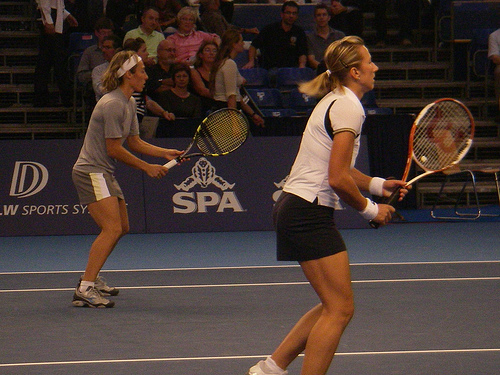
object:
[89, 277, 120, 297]
tennis shoes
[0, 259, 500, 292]
lines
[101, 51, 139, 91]
hair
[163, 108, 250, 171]
racket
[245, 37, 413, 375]
woman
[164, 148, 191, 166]
hand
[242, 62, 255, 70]
hand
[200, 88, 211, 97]
hand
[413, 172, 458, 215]
ground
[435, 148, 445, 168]
ground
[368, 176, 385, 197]
wrist sweatband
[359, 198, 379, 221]
wrist sweatband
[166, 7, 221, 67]
woman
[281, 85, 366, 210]
white t-shirt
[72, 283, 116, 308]
shoes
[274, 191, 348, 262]
shorts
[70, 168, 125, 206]
shorts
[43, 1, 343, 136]
crowd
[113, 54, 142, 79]
headband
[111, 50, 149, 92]
head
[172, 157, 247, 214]
advertisements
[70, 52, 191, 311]
woman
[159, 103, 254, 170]
tennis racket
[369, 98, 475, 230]
racket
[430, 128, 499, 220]
chair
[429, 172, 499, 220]
legs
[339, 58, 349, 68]
clip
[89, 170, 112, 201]
stripe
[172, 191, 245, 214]
spa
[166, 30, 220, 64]
shirt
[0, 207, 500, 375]
court